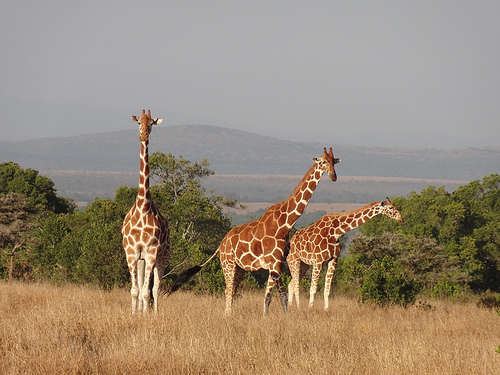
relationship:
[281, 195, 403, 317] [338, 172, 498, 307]
giraffe eating leaves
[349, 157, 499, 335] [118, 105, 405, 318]
trees behind giraffes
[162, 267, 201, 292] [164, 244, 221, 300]
tip of tail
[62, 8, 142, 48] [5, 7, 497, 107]
clouds in sky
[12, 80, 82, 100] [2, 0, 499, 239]
clouds in sky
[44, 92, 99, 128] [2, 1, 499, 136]
clouds in sky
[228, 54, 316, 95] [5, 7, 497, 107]
clouds in sky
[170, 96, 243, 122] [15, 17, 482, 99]
clouds in sky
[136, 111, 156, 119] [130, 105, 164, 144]
horns on head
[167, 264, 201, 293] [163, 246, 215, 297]
hair on tail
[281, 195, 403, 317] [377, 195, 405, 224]
giraffe has giraffe head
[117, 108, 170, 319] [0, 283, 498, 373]
giraffe in grass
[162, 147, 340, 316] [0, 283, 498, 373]
giraffe in grass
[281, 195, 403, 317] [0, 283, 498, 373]
giraffe in grass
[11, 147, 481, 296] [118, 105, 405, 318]
trees behind giraffes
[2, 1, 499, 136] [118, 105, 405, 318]
sky above giraffes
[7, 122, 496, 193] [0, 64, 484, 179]
mountains in distance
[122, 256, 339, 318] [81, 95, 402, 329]
legs on giraffes